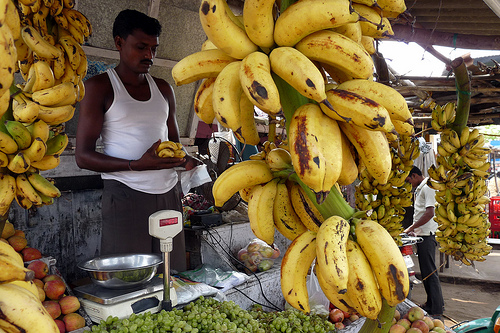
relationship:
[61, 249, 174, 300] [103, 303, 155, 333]
bowl sits on a scale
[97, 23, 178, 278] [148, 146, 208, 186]
man holding bananas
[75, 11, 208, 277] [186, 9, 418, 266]
man selling bananas